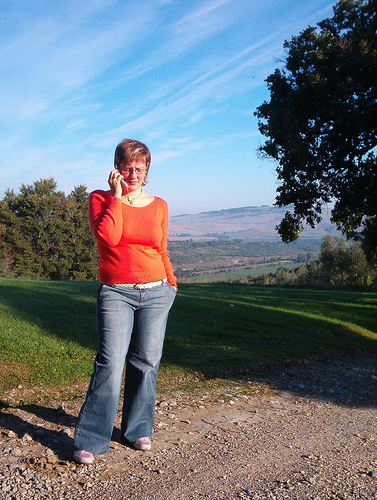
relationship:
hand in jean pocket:
[160, 233, 178, 290] [165, 282, 175, 305]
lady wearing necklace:
[65, 139, 177, 463] [123, 191, 143, 204]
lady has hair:
[65, 136, 184, 462] [104, 133, 157, 170]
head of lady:
[114, 135, 151, 189] [65, 136, 184, 462]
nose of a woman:
[131, 170, 135, 178] [74, 138, 177, 466]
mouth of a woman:
[126, 178, 141, 186] [74, 138, 177, 466]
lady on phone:
[65, 136, 184, 462] [103, 165, 159, 189]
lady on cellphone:
[65, 139, 177, 463] [116, 174, 132, 192]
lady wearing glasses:
[65, 136, 184, 462] [122, 164, 147, 180]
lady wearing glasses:
[65, 136, 184, 462] [118, 164, 146, 173]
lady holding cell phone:
[65, 136, 184, 462] [110, 166, 131, 188]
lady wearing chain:
[65, 136, 184, 462] [121, 193, 140, 210]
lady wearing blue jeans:
[65, 136, 184, 462] [73, 282, 178, 454]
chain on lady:
[121, 193, 140, 210] [65, 136, 184, 462]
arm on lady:
[88, 169, 127, 245] [65, 136, 184, 462]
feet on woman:
[72, 433, 154, 462] [74, 138, 177, 466]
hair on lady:
[114, 138, 152, 184] [65, 136, 184, 462]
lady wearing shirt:
[65, 136, 184, 462] [82, 189, 185, 291]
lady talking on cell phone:
[65, 136, 184, 462] [109, 164, 132, 192]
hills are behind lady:
[187, 204, 271, 262] [65, 136, 184, 462]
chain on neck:
[96, 181, 167, 223] [114, 181, 150, 197]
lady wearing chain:
[65, 136, 184, 462] [96, 181, 167, 223]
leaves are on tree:
[20, 210, 66, 244] [1, 176, 104, 281]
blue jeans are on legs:
[71, 282, 179, 453] [76, 284, 176, 447]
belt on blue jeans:
[111, 279, 168, 289] [73, 282, 178, 454]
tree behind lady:
[1, 176, 104, 281] [65, 139, 177, 463]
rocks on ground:
[160, 399, 371, 498] [1, 275, 376, 495]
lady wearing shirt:
[65, 136, 184, 462] [86, 188, 181, 294]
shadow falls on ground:
[197, 302, 313, 377] [201, 381, 364, 488]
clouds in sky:
[7, 19, 263, 188] [1, 2, 250, 136]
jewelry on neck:
[117, 188, 142, 205] [116, 189, 145, 194]